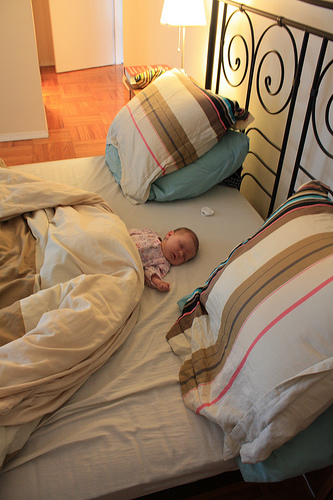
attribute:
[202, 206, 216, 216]
teether — white, plastic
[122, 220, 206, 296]
baby — girl, sleeping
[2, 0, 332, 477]
bed — large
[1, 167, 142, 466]
comforter — brown, white, crumpled, tan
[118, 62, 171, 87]
book — large, hard cover, red, hardcover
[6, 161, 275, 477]
sheet — white, cotton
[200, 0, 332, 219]
bed frame — black, metal, wrought iron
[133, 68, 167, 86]
bag — colorful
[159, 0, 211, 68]
lamp — white, glowing, turned on, on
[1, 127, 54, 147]
baseboard — white, clean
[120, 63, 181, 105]
table — brass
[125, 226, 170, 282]
onesie — pink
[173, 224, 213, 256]
hair — dark brown, fine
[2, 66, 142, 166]
floor — wooden, medium brown, brown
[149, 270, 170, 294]
arm — tiny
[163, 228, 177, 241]
ear — tiny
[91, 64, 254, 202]
pillow — striped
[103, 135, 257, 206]
pillow — blue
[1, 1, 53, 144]
wall — beige, white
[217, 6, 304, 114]
curls — round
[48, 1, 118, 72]
door — white, open